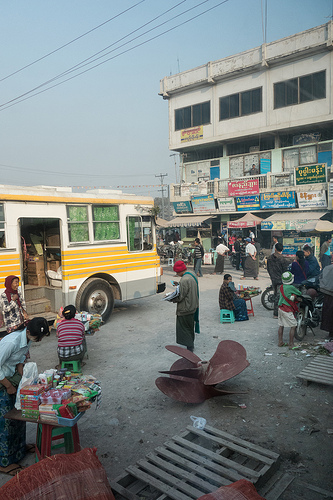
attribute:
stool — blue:
[216, 307, 238, 326]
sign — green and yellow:
[282, 159, 330, 185]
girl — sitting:
[214, 272, 262, 323]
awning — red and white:
[216, 192, 283, 239]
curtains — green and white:
[87, 203, 125, 243]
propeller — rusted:
[142, 327, 255, 405]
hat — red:
[170, 258, 186, 273]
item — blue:
[189, 414, 207, 430]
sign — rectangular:
[292, 162, 330, 186]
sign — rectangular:
[227, 180, 258, 198]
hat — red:
[159, 245, 200, 281]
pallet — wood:
[144, 436, 210, 476]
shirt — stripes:
[47, 310, 82, 353]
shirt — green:
[277, 284, 299, 306]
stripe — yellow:
[0, 245, 126, 259]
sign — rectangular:
[294, 163, 330, 182]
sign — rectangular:
[295, 188, 328, 209]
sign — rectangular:
[260, 189, 296, 209]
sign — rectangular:
[190, 195, 214, 211]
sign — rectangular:
[169, 199, 191, 214]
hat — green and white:
[280, 269, 295, 285]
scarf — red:
[2, 286, 23, 302]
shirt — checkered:
[0, 289, 29, 337]